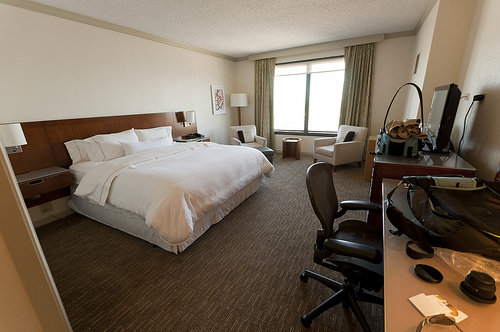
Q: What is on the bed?
A: Blankets and pillows.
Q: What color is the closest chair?
A: Black.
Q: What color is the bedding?
A: White.